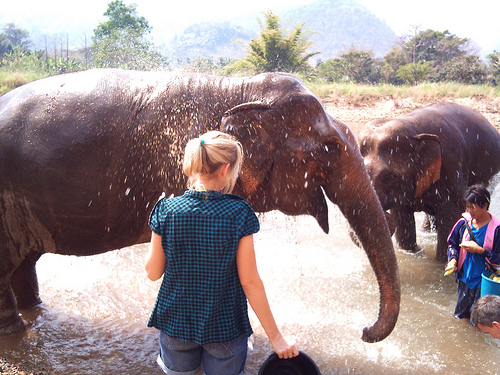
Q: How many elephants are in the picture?
A: Two.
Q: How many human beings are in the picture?
A: Two.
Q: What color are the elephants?
A: Brown.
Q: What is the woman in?
A: She is in the water.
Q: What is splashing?
A: The water is splashing.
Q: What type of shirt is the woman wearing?
A: A short sleeved shirt.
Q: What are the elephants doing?
A: It is bath time for the elephants.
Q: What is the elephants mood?
A: Happy and smiling.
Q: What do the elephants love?
A: The love their bath.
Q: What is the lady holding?
A: The lady is holding a bucket.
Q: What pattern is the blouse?
A: The blouse is checkered.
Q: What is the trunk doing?
A: Splashing water.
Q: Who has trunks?
A: The elephants.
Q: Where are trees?
A: In the distance.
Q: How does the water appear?
A: Murky.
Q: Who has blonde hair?
A: Woman on left.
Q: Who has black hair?
A: Woman on right.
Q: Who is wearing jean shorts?
A: Blonde woman.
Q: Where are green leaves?
A: On the trees.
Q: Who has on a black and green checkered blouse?
A: The blonde woman.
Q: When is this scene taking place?
A: Daytime.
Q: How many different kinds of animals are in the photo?
A: One.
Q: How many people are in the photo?
A: Two.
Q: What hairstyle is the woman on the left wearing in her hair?
A: Ponytail.